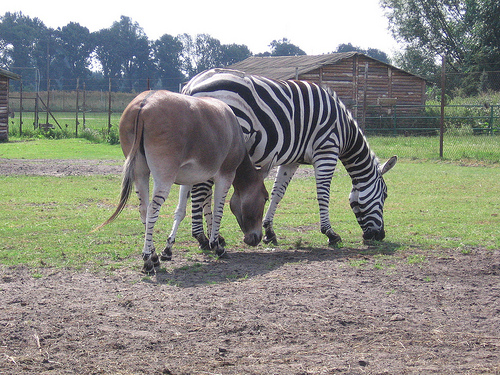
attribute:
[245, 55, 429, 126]
building — in background, log, small, old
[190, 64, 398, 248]
zebra — eating grass, grazing, beautifu, in field, black, white, fenced in, a mother, in captivity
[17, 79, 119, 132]
fence — behind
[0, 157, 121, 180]
patch — dirt, bare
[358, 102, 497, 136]
fence — in front of building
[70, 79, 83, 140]
wood — tall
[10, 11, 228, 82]
tree line — in distance, in line, many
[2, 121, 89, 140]
flowers — growing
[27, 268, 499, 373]
dirt — brown, scarce, bare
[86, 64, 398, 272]
zebras — beautiful, not happy, grazing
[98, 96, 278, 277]
donkey — brown, white, a baby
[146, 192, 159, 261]
stripe — black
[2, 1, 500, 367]
scenario — wrong, surrounded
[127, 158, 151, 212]
leg — brown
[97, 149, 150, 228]
hair — long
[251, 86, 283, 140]
stripes — black, white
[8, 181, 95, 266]
grass — green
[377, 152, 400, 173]
ear — on zebra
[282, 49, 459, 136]
barn — wooden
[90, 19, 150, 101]
tree — large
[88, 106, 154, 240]
tail — long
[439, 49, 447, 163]
post — wooden